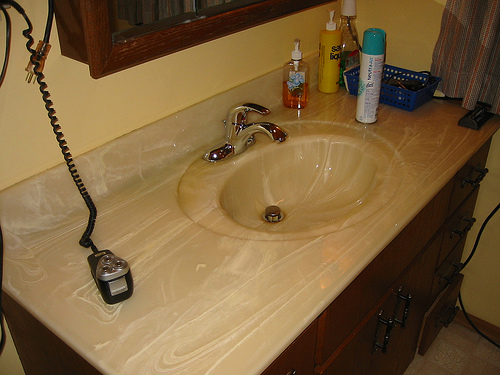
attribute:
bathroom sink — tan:
[172, 98, 407, 244]